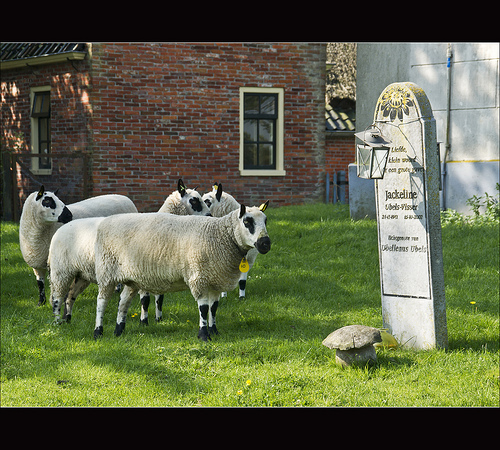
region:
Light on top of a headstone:
[351, 122, 396, 189]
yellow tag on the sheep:
[236, 248, 251, 276]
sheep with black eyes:
[235, 205, 281, 257]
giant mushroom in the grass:
[313, 310, 398, 379]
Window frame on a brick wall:
[238, 83, 290, 182]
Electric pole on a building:
[438, 47, 455, 198]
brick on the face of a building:
[99, 49, 216, 196]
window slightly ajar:
[27, 90, 60, 121]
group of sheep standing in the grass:
[15, 163, 273, 349]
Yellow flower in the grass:
[222, 371, 256, 403]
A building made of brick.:
[111, 53, 231, 165]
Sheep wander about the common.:
[17, 144, 277, 336]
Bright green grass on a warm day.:
[172, 347, 304, 396]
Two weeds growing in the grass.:
[227, 368, 267, 403]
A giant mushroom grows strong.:
[322, 312, 390, 369]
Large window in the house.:
[234, 79, 288, 189]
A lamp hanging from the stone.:
[345, 115, 397, 187]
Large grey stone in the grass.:
[367, 65, 459, 362]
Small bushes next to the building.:
[442, 187, 494, 225]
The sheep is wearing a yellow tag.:
[211, 196, 275, 298]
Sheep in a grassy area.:
[18, 176, 273, 354]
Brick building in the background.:
[3, 43, 363, 225]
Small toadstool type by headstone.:
[320, 320, 387, 371]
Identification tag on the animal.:
[235, 248, 252, 275]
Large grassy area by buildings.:
[2, 198, 498, 410]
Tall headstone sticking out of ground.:
[361, 73, 452, 360]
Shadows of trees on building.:
[3, 49, 95, 221]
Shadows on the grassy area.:
[0, 215, 499, 385]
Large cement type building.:
[345, 44, 499, 226]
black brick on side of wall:
[154, 107, 175, 118]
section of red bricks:
[143, 57, 209, 83]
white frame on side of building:
[225, 74, 302, 182]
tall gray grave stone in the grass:
[363, 74, 464, 363]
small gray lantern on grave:
[344, 126, 390, 181]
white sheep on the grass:
[89, 202, 288, 334]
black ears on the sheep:
[162, 175, 189, 194]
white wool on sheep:
[109, 221, 183, 263]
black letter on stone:
[410, 188, 418, 200]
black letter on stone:
[407, 190, 414, 202]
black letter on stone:
[406, 188, 411, 200]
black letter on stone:
[401, 186, 408, 198]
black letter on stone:
[398, 188, 404, 199]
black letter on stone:
[393, 188, 400, 200]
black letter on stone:
[391, 190, 396, 198]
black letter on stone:
[385, 191, 394, 198]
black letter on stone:
[381, 187, 389, 204]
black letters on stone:
[380, 187, 423, 204]